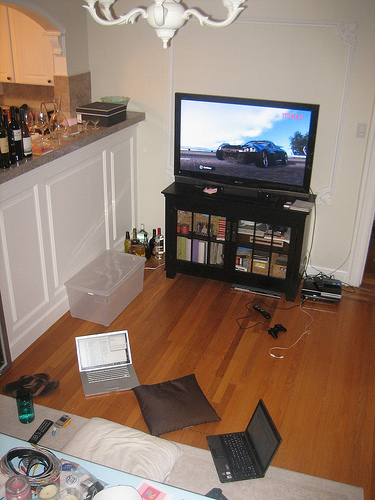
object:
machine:
[301, 272, 344, 306]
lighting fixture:
[81, 0, 252, 51]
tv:
[173, 91, 321, 201]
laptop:
[74, 329, 141, 403]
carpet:
[0, 392, 364, 499]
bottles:
[19, 108, 35, 161]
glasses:
[35, 109, 49, 148]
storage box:
[61, 246, 149, 329]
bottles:
[155, 227, 165, 259]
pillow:
[129, 369, 228, 444]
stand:
[161, 178, 317, 305]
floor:
[0, 262, 375, 498]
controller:
[28, 418, 56, 444]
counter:
[0, 108, 147, 186]